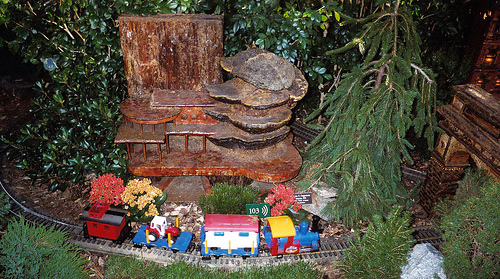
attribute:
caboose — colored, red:
[80, 203, 132, 243]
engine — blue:
[262, 214, 320, 256]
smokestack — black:
[311, 215, 319, 233]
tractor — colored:
[145, 216, 180, 244]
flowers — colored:
[89, 173, 164, 217]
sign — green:
[246, 202, 269, 217]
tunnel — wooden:
[417, 83, 500, 218]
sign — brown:
[295, 192, 312, 204]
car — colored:
[200, 213, 260, 260]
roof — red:
[204, 213, 257, 230]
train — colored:
[80, 204, 322, 258]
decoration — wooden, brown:
[112, 12, 308, 200]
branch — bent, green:
[296, 1, 440, 236]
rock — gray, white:
[399, 241, 448, 278]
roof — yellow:
[267, 214, 296, 238]